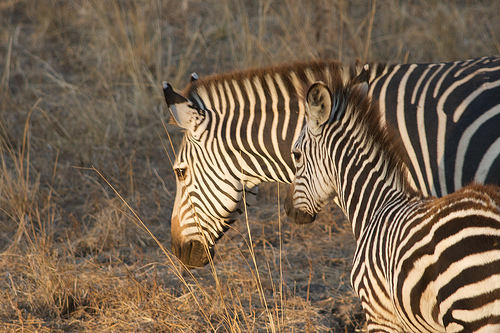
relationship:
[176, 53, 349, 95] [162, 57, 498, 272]
mane on zebra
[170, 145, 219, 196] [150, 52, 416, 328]
eye of zebra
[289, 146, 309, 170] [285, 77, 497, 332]
eye on zebra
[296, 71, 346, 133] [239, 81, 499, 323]
left ear on zebra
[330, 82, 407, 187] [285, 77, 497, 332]
mane on zebra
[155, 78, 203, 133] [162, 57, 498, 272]
ear on zebra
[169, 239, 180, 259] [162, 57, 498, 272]
nose of zebra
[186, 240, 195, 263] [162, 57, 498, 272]
mouth of zebra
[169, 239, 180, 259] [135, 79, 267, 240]
nose of zebra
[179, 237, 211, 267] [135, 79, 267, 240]
mouth of zebra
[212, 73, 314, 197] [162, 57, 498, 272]
neck of zebra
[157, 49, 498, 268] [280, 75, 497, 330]
mother and baby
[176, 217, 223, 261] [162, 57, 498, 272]
nose on zebra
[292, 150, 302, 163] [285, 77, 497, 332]
eye on zebra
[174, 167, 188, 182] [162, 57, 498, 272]
eye on zebra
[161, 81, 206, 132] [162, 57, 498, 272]
ear on zebra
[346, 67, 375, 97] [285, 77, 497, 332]
ear on zebra